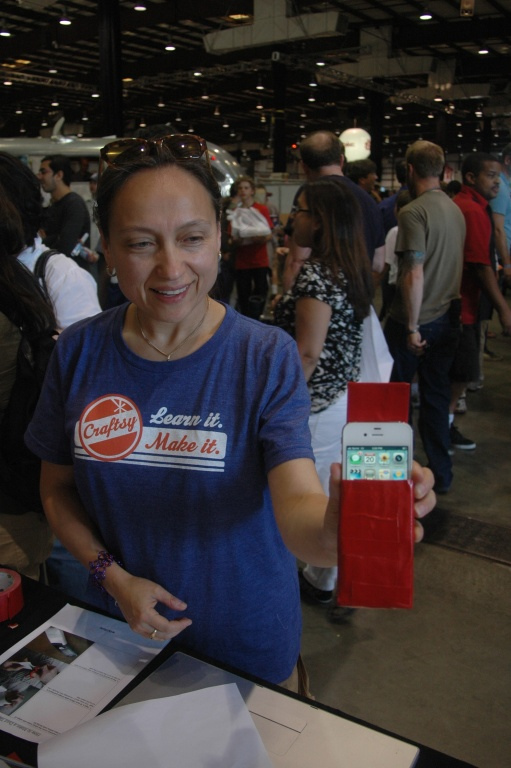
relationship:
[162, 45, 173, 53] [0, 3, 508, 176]
light on ceiling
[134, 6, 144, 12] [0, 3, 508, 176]
light on ceiling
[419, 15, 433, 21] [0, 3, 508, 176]
light on ceiling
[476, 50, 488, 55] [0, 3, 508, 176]
light on ceiling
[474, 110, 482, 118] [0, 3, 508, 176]
light on ceiling